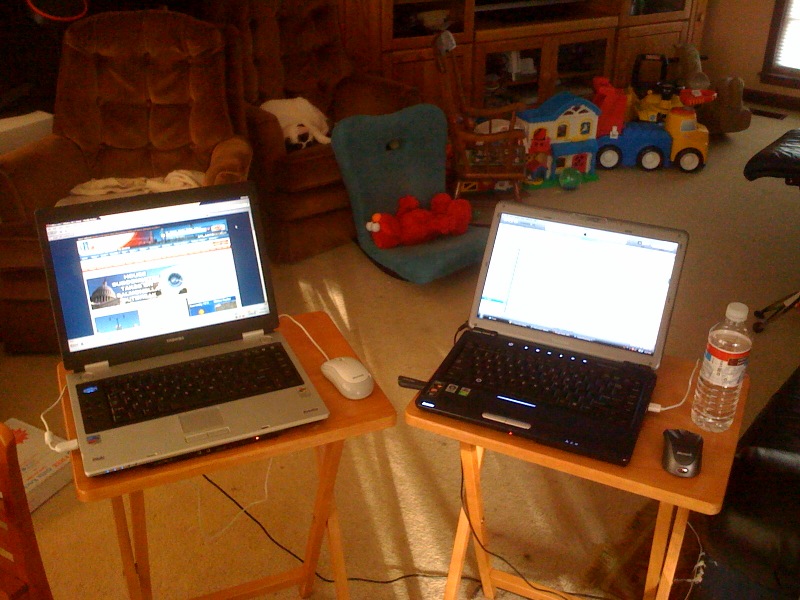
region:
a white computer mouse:
[280, 311, 402, 411]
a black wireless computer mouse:
[657, 421, 715, 489]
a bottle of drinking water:
[684, 285, 751, 441]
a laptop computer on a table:
[421, 191, 670, 484]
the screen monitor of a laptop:
[25, 194, 289, 370]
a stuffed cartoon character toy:
[353, 173, 501, 280]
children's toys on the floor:
[512, 65, 754, 220]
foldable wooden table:
[33, 315, 429, 597]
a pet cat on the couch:
[234, 82, 357, 224]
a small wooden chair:
[424, 26, 549, 234]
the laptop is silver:
[43, 181, 324, 475]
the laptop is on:
[417, 201, 689, 471]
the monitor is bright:
[476, 208, 671, 356]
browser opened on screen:
[50, 196, 266, 348]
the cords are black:
[202, 460, 600, 599]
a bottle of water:
[693, 302, 745, 433]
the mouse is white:
[316, 355, 375, 403]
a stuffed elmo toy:
[365, 192, 469, 249]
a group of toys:
[514, 76, 706, 186]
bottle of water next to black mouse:
[693, 296, 753, 432]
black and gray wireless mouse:
[659, 424, 708, 482]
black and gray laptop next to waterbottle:
[411, 196, 689, 470]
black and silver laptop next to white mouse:
[32, 179, 341, 477]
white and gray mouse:
[279, 306, 379, 402]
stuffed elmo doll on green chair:
[333, 99, 497, 284]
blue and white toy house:
[520, 92, 602, 194]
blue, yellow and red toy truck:
[586, 79, 711, 179]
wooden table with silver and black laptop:
[52, 307, 402, 599]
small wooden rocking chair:
[429, 28, 527, 230]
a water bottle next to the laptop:
[689, 299, 756, 433]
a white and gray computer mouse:
[316, 350, 388, 408]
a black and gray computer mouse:
[663, 425, 717, 493]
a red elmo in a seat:
[358, 177, 482, 257]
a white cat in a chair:
[264, 82, 341, 157]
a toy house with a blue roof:
[508, 94, 614, 194]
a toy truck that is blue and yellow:
[593, 85, 729, 182]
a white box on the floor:
[4, 407, 84, 522]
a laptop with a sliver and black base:
[28, 185, 327, 479]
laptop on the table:
[424, 182, 677, 473]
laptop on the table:
[25, 184, 334, 469]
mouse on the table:
[320, 346, 369, 400]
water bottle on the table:
[690, 297, 752, 438]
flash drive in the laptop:
[389, 358, 426, 396]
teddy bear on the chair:
[364, 176, 463, 246]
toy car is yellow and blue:
[573, 66, 711, 168]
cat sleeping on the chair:
[265, 80, 329, 163]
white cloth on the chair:
[77, 162, 214, 206]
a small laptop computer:
[422, 166, 680, 499]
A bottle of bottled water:
[690, 295, 755, 436]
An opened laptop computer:
[28, 177, 334, 482]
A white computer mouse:
[314, 352, 383, 403]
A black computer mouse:
[656, 420, 707, 489]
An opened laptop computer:
[411, 173, 686, 478]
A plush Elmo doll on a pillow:
[344, 181, 480, 251]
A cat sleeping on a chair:
[252, 88, 337, 154]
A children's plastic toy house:
[506, 83, 606, 192]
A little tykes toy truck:
[594, 80, 714, 174]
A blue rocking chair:
[326, 105, 508, 286]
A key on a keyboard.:
[530, 374, 542, 384]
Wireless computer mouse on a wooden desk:
[660, 425, 708, 481]